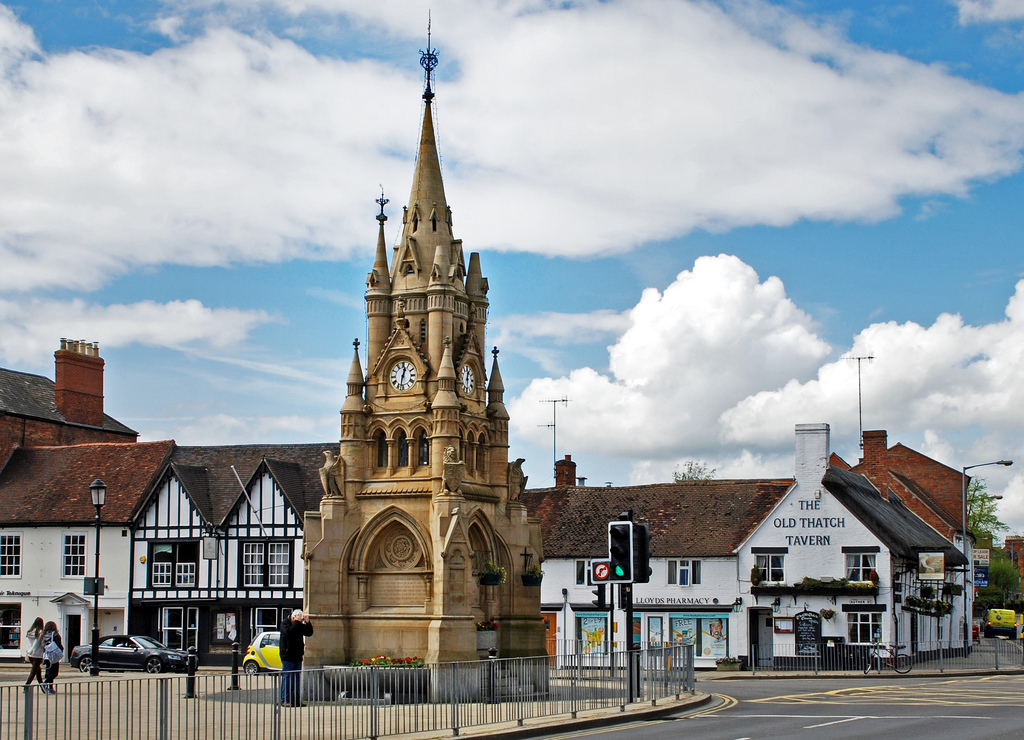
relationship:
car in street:
[73, 611, 195, 678] [13, 607, 1018, 737]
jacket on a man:
[276, 619, 313, 659] [274, 605, 313, 705]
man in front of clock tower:
[274, 605, 313, 705] [298, 3, 549, 701]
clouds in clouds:
[4, 9, 1020, 543] [0, 0, 1024, 543]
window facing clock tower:
[60, 536, 87, 576] [298, 3, 549, 701]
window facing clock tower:
[2, 532, 22, 574] [298, 3, 549, 701]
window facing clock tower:
[147, 532, 178, 587] [298, 3, 549, 701]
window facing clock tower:
[177, 539, 197, 587] [298, 3, 549, 701]